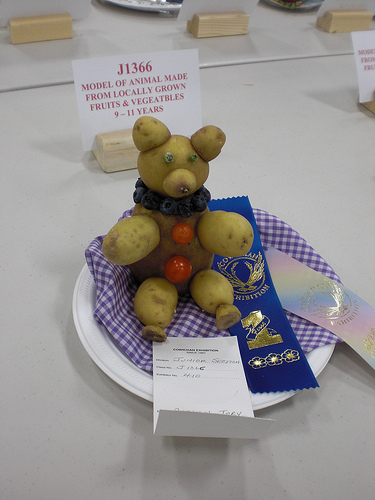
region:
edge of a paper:
[212, 413, 231, 434]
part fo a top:
[313, 391, 335, 421]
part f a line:
[208, 371, 224, 397]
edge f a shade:
[256, 439, 267, 456]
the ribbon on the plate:
[210, 188, 305, 399]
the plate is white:
[66, 264, 338, 416]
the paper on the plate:
[141, 329, 272, 443]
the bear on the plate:
[103, 109, 261, 335]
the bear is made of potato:
[103, 111, 269, 332]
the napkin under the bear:
[82, 232, 346, 363]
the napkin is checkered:
[78, 190, 353, 357]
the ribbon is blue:
[202, 193, 310, 403]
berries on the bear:
[128, 186, 228, 213]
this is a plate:
[71, 210, 365, 417]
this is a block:
[97, 129, 166, 174]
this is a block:
[176, 5, 258, 46]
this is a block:
[4, 7, 82, 53]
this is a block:
[179, 4, 251, 43]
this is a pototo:
[189, 263, 231, 306]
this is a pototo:
[76, 187, 154, 272]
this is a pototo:
[198, 199, 248, 256]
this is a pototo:
[123, 109, 183, 155]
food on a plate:
[120, 135, 258, 303]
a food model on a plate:
[136, 154, 275, 335]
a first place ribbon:
[182, 203, 327, 439]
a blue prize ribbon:
[207, 210, 320, 436]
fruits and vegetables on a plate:
[110, 102, 317, 400]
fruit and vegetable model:
[115, 120, 307, 351]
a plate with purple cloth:
[97, 141, 300, 439]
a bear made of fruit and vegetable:
[105, 122, 372, 422]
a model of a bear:
[111, 118, 264, 368]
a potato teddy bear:
[98, 114, 254, 342]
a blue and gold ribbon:
[205, 194, 321, 394]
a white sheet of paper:
[151, 334, 278, 441]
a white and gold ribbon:
[257, 243, 374, 370]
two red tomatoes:
[161, 222, 194, 284]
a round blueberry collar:
[130, 174, 211, 216]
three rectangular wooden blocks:
[7, 9, 373, 44]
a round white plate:
[72, 205, 345, 413]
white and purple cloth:
[82, 205, 347, 383]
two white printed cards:
[70, 28, 374, 153]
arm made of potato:
[101, 215, 159, 263]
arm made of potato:
[198, 212, 252, 257]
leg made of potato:
[190, 267, 241, 328]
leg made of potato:
[132, 275, 177, 341]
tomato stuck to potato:
[166, 255, 191, 280]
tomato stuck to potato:
[171, 225, 192, 245]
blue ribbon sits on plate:
[204, 192, 322, 397]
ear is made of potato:
[191, 125, 226, 162]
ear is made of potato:
[132, 113, 171, 157]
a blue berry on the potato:
[162, 197, 173, 213]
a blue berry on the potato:
[177, 201, 185, 209]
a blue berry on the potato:
[205, 184, 217, 195]